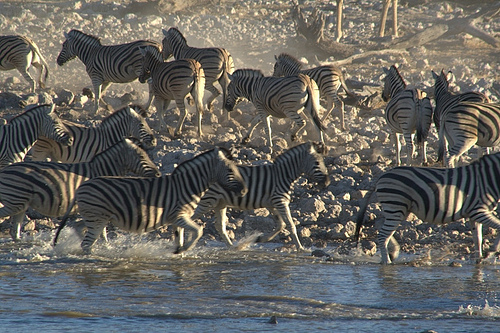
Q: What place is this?
A: It is a river.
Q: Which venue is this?
A: This is a river.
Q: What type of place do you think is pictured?
A: It is a river.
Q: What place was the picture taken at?
A: It was taken at the river.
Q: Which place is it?
A: It is a river.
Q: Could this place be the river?
A: Yes, it is the river.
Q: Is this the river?
A: Yes, it is the river.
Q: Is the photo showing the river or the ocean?
A: It is showing the river.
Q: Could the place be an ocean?
A: No, it is a river.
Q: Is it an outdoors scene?
A: Yes, it is outdoors.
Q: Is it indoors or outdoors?
A: It is outdoors.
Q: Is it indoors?
A: No, it is outdoors.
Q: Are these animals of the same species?
A: Yes, all the animals are zebras.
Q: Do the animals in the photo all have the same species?
A: Yes, all the animals are zebras.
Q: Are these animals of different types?
A: No, all the animals are zebras.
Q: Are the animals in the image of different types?
A: No, all the animals are zebras.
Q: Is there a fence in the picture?
A: No, there are no fences.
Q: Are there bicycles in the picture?
A: No, there are no bicycles.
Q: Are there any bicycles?
A: No, there are no bicycles.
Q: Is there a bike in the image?
A: No, there are no bikes.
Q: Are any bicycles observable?
A: No, there are no bicycles.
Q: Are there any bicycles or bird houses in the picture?
A: No, there are no bicycles or bird houses.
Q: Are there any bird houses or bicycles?
A: No, there are no bicycles or bird houses.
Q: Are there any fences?
A: No, there are no fences.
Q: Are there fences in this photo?
A: No, there are no fences.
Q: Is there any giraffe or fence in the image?
A: No, there are no fences or giraffes.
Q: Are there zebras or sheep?
A: Yes, there is a zebra.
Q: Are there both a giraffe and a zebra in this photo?
A: No, there is a zebra but no giraffes.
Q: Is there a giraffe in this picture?
A: No, there are no giraffes.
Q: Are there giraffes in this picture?
A: No, there are no giraffes.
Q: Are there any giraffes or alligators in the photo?
A: No, there are no giraffes or alligators.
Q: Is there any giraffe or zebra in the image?
A: Yes, there are zebras.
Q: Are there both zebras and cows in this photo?
A: No, there are zebras but no cows.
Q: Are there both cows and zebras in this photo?
A: No, there are zebras but no cows.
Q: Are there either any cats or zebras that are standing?
A: Yes, the zebras are standing.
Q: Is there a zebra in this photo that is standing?
A: Yes, there are zebras that are standing.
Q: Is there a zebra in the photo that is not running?
A: Yes, there are zebras that are standing.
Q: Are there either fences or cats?
A: No, there are no fences or cats.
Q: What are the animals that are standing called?
A: The animals are zebras.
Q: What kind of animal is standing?
A: The animal is zebras.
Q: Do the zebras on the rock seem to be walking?
A: No, the zebras are standing.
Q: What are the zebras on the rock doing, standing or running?
A: The zebras are standing.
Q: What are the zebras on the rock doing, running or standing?
A: The zebras are standing.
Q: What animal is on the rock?
A: The zebras are on the rock.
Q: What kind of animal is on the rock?
A: The animals are zebras.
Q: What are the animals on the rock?
A: The animals are zebras.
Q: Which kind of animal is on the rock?
A: The animals are zebras.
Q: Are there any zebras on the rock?
A: Yes, there are zebras on the rock.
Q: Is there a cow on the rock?
A: No, there are zebras on the rock.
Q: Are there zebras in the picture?
A: Yes, there is a zebra.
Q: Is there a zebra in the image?
A: Yes, there is a zebra.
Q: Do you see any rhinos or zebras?
A: Yes, there is a zebra.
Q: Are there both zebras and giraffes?
A: No, there is a zebra but no giraffes.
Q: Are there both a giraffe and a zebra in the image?
A: No, there is a zebra but no giraffes.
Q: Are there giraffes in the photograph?
A: No, there are no giraffes.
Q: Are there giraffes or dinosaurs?
A: No, there are no giraffes or dinosaurs.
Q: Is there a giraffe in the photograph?
A: No, there are no giraffes.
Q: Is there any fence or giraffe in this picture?
A: No, there are no giraffes or fences.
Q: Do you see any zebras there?
A: Yes, there is a zebra.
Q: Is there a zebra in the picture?
A: Yes, there is a zebra.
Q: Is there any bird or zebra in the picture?
A: Yes, there is a zebra.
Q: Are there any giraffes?
A: No, there are no giraffes.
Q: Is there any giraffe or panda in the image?
A: No, there are no giraffes or pandas.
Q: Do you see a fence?
A: No, there are no fences.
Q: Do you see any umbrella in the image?
A: No, there are no umbrellas.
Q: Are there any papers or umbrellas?
A: No, there are no umbrellas or papers.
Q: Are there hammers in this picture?
A: No, there are no hammers.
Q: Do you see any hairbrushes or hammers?
A: No, there are no hammers or hairbrushes.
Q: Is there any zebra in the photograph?
A: Yes, there is a zebra.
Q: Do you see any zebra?
A: Yes, there is a zebra.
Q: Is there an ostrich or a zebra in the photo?
A: Yes, there is a zebra.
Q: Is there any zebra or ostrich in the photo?
A: Yes, there is a zebra.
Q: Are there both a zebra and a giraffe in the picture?
A: No, there is a zebra but no giraffes.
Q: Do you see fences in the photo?
A: No, there are no fences.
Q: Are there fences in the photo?
A: No, there are no fences.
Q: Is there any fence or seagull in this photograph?
A: No, there are no fences or seagulls.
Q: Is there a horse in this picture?
A: No, there are no horses.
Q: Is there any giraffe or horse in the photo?
A: No, there are no horses or giraffes.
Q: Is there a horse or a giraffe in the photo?
A: No, there are no horses or giraffes.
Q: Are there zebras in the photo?
A: Yes, there is a zebra.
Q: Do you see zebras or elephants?
A: Yes, there is a zebra.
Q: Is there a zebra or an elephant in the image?
A: Yes, there is a zebra.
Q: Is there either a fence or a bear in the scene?
A: No, there are no fences or bears.